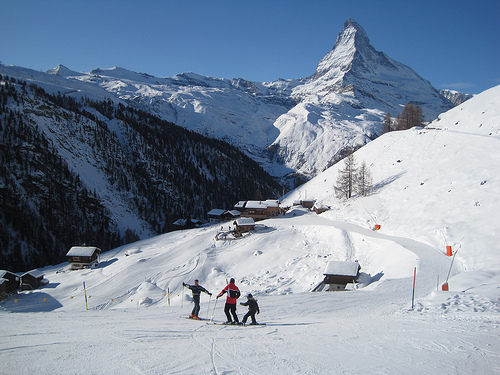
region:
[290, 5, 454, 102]
a tall snow covered mountain.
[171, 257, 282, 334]
people enjoying a day on a snow covered slope.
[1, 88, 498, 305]
a ski slope covered in snow.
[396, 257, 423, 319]
a flag on the side of a snow covered slope.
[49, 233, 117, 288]
a small house on a snow covered slope.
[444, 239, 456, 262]
an orange flag in the snow.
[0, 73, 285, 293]
trees on the side of a snow covered ski slope.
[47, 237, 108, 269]
a small snow covered building.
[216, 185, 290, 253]
three small wooden structure.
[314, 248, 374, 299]
a small house.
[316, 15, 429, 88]
Snow covered mountain peak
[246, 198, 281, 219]
A snow covered house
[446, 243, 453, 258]
A bright orange barrel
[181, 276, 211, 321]
The person is wearing skis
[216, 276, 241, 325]
A person wearing a red coat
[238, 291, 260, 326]
A kid wearing a toboggan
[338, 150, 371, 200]
The trees are bare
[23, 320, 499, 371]
Tracks are in the snow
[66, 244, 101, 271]
A small building with a snow covered roof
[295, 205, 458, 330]
The road is covered with snow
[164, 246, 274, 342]
people are going snowboarding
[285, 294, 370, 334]
snow is on the ground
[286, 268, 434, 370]
the snow is white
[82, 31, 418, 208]
mountains with snow on them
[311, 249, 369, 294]
roof covered with snow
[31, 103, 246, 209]
trees on the mountain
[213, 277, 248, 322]
person wearing orange jacket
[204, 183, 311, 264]
houses in the distance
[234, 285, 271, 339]
child going snowboarding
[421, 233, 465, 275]
orange basket in the snow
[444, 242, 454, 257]
Orange safety cone attached to pole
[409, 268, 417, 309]
Multi colored pole for guidance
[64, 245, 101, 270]
Small building with snow on roof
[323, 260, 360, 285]
Small wooden buiding in snow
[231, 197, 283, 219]
Large house in background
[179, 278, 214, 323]
Person standing with skis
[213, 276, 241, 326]
Person in red coat skiing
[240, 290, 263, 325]
Little kid playing in snow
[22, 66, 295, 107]
Large snow covered mountain ridge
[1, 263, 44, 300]
Small group of buildings in vally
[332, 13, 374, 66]
peak of a mountain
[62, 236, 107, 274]
small ski cabin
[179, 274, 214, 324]
person on downhill skis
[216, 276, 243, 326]
person in red parka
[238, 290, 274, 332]
child on alpine skis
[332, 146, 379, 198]
pine trees on the mountainside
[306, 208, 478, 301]
snowy winding roadway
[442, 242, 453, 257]
orange road marker on side of road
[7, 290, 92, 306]
orange trail flags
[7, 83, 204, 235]
mountainside filled with pine trees